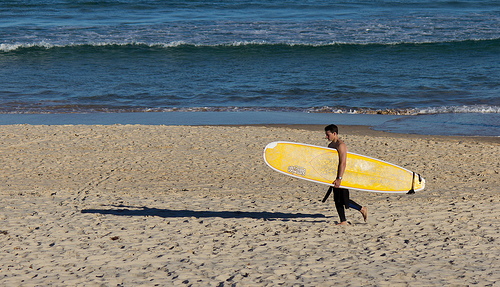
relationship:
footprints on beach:
[395, 222, 499, 255] [1, 0, 498, 285]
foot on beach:
[360, 205, 370, 224] [0, 112, 492, 284]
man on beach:
[323, 123, 369, 227] [0, 112, 492, 284]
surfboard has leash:
[263, 139, 338, 186] [409, 169, 415, 195]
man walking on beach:
[323, 123, 369, 227] [1, 0, 498, 285]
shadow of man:
[81, 200, 335, 225] [323, 123, 369, 227]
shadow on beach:
[81, 200, 335, 225] [1, 0, 498, 285]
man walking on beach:
[320, 123, 372, 229] [0, 112, 492, 284]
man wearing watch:
[320, 123, 372, 229] [334, 174, 346, 184]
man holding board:
[323, 123, 369, 227] [260, 141, 427, 195]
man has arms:
[323, 123, 369, 227] [335, 142, 346, 179]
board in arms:
[260, 141, 427, 195] [335, 142, 346, 179]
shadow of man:
[81, 200, 335, 225] [314, 114, 365, 220]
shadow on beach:
[81, 200, 335, 225] [0, 112, 492, 284]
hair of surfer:
[322, 119, 343, 139] [315, 121, 370, 226]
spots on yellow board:
[286, 147, 408, 192] [265, 138, 475, 217]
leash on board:
[405, 169, 422, 195] [260, 137, 457, 194]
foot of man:
[330, 214, 357, 226] [323, 123, 369, 227]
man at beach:
[323, 123, 369, 227] [0, 112, 492, 284]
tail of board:
[401, 168, 431, 199] [261, 128, 427, 202]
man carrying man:
[323, 123, 369, 227] [323, 123, 369, 227]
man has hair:
[320, 123, 372, 229] [314, 110, 359, 147]